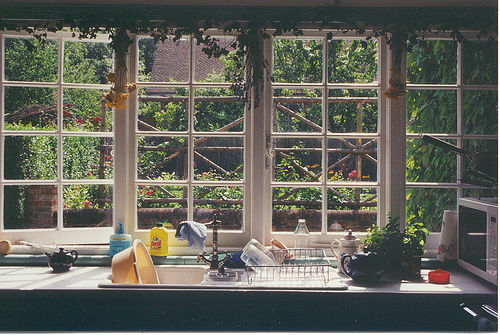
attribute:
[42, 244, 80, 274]
teapot — brown, small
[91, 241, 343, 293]
sink — metal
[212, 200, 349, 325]
dish rack — white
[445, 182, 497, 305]
microoven — white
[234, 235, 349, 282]
bottles — white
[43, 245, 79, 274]
tea pot — small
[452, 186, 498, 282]
microwave — white, oven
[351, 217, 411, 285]
houseplant — is green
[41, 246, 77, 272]
teapot — small, black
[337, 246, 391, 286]
tea pot — is black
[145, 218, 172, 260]
bottle — yellow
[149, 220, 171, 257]
bottle — yellow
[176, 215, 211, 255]
towel — blue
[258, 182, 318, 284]
bottle — clear, glass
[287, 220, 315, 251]
jar — glass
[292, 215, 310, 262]
bottle — clear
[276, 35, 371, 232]
window — paned glass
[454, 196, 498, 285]
microwave — white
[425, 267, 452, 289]
tin — red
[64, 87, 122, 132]
window pane — white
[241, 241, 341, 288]
dish — white, plastic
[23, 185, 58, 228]
pillar — brick